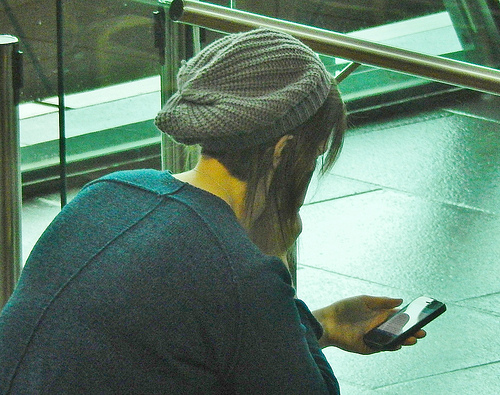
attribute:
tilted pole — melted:
[168, 0, 498, 96]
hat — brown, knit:
[119, 33, 301, 140]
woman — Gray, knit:
[35, 18, 432, 393]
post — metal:
[2, 39, 63, 237]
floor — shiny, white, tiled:
[357, 90, 497, 276]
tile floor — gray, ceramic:
[16, 84, 499, 391]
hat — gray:
[147, 38, 334, 157]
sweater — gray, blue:
[9, 122, 363, 391]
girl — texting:
[70, 14, 387, 382]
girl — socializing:
[136, 23, 343, 387]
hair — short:
[211, 151, 254, 173]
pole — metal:
[395, 23, 492, 113]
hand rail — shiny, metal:
[161, 5, 498, 115]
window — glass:
[1, 0, 492, 136]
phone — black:
[362, 294, 447, 354]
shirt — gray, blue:
[3, 167, 343, 391]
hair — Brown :
[207, 98, 349, 248]